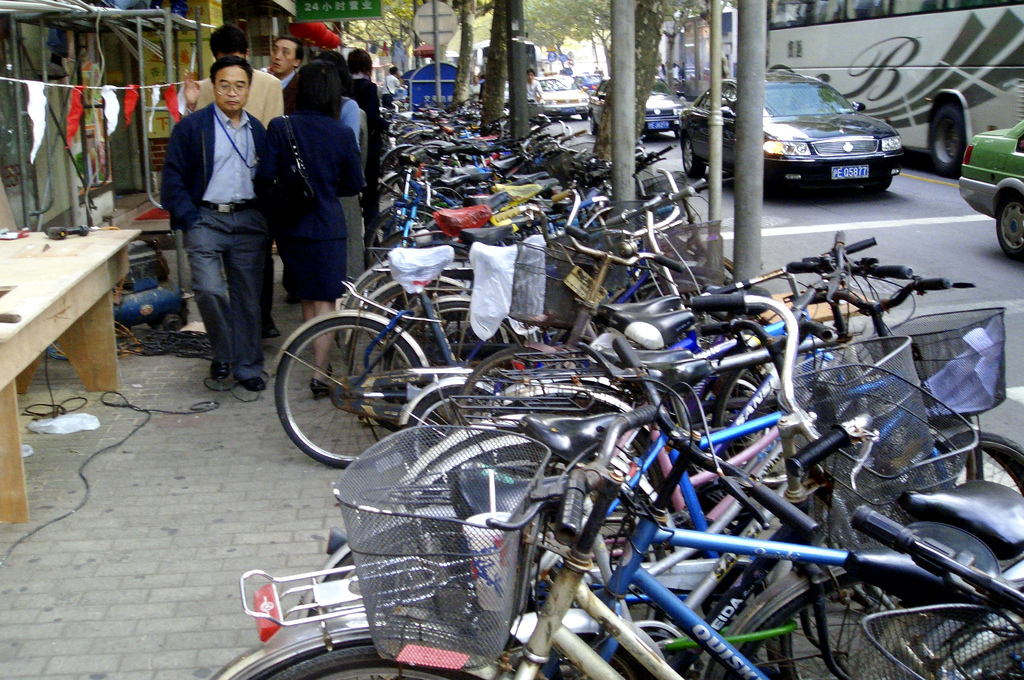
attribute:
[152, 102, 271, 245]
jacket — blue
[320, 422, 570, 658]
basket — silver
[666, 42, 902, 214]
car — black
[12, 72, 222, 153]
flags — white, red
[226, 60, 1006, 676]
line — large